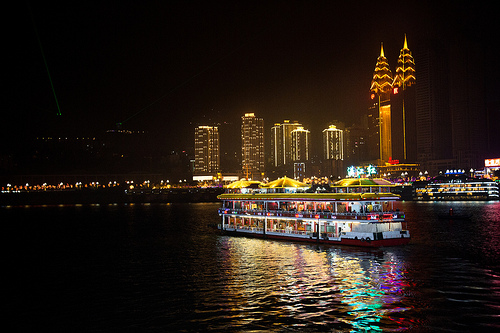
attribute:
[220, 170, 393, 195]
lights — neon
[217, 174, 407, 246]
ship — cruise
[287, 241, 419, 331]
lights — colorful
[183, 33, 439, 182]
buildings — shorter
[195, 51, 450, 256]
boat — tourist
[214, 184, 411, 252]
boat — tourist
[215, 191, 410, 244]
ship — cruise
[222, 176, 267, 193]
umbrella — yellow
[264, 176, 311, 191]
umbrella — yellow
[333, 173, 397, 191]
umbrella — yellow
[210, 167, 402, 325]
lights — neon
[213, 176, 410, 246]
boat — party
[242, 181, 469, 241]
boat — tourist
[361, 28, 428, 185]
building — tall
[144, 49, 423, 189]
buildings — tall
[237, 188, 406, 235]
lights — neon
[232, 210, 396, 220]
lights — multi-colored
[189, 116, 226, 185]
building — big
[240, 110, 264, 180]
building — big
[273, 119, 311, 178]
building — big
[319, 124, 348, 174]
building — big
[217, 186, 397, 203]
roof — yellow